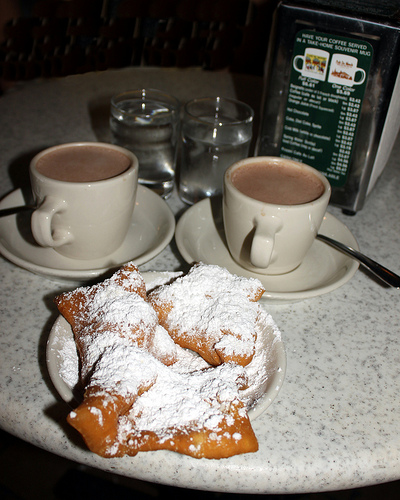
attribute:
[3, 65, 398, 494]
table — white, round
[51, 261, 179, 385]
pastry — sugared, with sugar, powdered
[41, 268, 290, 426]
plate — white, small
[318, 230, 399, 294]
spoon — stainless steel, silver, with handle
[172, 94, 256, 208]
glass — clear, cold, full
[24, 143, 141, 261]
cup — white, holding chocolate, full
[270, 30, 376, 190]
sign — green, illegible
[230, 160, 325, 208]
coffee — milked, brown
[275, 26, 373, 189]
menu — green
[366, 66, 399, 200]
napkin — white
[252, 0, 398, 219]
napkin dispenser — metal